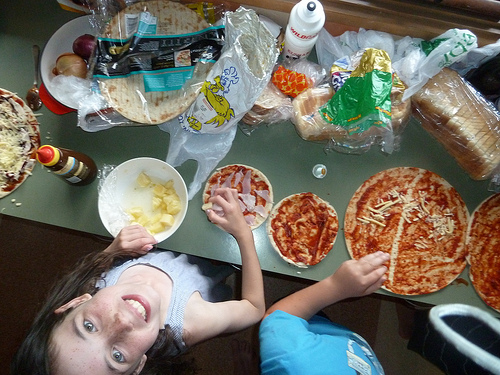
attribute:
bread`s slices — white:
[409, 66, 498, 182]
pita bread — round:
[80, 0, 221, 121]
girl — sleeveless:
[14, 185, 264, 372]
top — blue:
[93, 250, 233, 350]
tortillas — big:
[84, 2, 225, 127]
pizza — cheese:
[301, 130, 440, 305]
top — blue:
[260, 311, 388, 373]